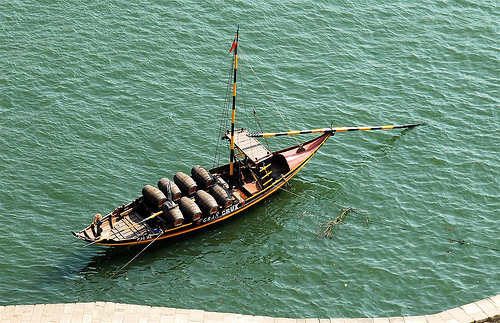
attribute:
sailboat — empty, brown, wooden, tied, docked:
[60, 114, 354, 264]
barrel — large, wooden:
[139, 180, 168, 204]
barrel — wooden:
[157, 173, 184, 196]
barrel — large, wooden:
[173, 165, 202, 195]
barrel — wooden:
[189, 163, 223, 186]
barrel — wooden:
[159, 197, 185, 225]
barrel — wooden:
[182, 196, 205, 221]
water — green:
[19, 22, 468, 310]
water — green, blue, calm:
[269, 11, 473, 106]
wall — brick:
[2, 291, 485, 320]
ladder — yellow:
[257, 161, 274, 185]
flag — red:
[228, 38, 238, 54]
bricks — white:
[461, 298, 494, 320]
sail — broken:
[221, 102, 444, 172]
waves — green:
[293, 31, 490, 94]